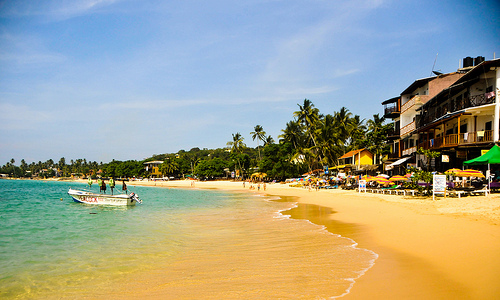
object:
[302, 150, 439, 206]
people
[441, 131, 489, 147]
balcony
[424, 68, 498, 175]
house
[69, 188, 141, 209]
boat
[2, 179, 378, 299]
water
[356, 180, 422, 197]
fence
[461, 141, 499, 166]
canopy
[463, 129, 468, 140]
towel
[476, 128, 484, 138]
towel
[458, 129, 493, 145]
balcony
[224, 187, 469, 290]
beach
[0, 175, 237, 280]
water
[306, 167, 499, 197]
people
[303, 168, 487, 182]
umbrellas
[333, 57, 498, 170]
buildings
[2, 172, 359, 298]
ocean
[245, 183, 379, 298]
wave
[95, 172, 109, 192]
person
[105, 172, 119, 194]
person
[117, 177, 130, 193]
person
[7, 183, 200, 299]
blue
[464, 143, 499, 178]
umbrella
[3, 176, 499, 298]
sand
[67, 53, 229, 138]
clouds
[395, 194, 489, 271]
sand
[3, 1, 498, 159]
blue sky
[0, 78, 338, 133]
clouds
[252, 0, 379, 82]
clouds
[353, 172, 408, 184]
umbrellas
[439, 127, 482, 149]
balcony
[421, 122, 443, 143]
people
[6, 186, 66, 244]
water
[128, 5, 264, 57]
sky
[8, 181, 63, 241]
ocean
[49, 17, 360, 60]
sky